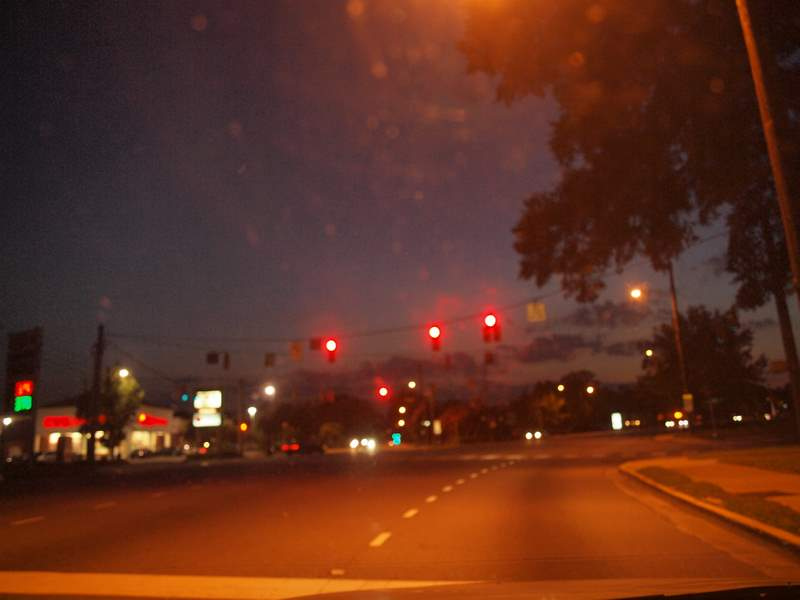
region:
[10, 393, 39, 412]
lights that are green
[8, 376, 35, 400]
light that is red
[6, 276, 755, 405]
lights hanging on wire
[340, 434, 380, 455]
car with lights on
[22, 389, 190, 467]
house with lights on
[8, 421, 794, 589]
road with line in middle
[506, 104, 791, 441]
trees on side of light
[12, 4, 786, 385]
clouds in the sky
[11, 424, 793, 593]
sidewalk on side of road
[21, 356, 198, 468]
tree in front of house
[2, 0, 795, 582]
looking through a dirty windshield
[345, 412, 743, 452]
headlights of oncoming traffic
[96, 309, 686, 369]
traffic lights directing traffic to stop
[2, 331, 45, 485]
gas station sign with digital gas pricing display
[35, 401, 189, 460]
the corner convenient store, across the road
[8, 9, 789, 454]
city skyline at dawn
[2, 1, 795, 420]
city skyline at dusk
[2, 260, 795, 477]
city lights at night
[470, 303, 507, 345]
the light is redthe light is red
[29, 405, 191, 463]
the store has light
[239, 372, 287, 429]
the lights are white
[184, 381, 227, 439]
advertisement boards are color white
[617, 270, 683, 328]
light on a pole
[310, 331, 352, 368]
traffic light hangs from a wire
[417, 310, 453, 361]
traffic light hangs from a wire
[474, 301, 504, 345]
traffic light hangs from a wire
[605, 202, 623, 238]
green leaves on the tree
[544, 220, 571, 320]
green leaves on the tree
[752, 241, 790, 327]
green leaves on the tree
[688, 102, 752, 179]
green leaves on the tree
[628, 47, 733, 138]
green leaves on the tree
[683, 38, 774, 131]
green leaves on the tree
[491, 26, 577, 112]
green leaves on the tree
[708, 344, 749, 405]
green leaves on the tree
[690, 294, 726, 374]
green leaves on the tree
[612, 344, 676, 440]
green leaves on the tree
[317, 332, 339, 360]
red stoplight farthest to left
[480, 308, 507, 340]
red stoplight farthest to right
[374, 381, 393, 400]
red stoplight in distance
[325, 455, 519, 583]
dashed line painted in middle of road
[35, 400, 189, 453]
retail business on left side of road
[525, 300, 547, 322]
white sign hanging above road